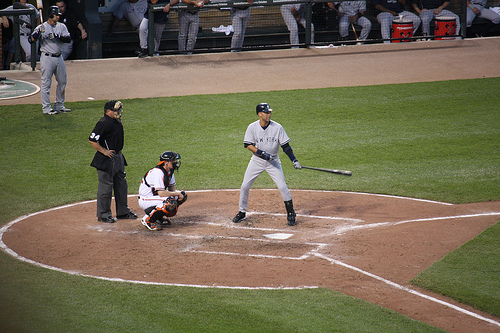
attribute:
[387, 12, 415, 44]
cooler — red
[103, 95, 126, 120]
mask — white, face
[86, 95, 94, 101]
spot — white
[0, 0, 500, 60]
people — sitting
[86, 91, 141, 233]
umpire — all in black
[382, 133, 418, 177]
ground — marked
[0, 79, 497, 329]
grass — short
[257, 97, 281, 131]
head — man's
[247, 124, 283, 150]
uniform — gray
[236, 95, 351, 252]
man — wearing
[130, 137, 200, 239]
man — wearing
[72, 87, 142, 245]
man — wearing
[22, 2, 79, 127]
man — wearing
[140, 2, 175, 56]
man — wearing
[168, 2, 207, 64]
man — wearing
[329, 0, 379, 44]
man — wearing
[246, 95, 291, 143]
baseball player — Yankees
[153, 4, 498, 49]
fence — black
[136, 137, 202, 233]
catcher — crouched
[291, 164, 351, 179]
bat — baseball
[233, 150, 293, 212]
pants — player's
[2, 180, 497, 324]
chalk — white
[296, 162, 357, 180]
bat — large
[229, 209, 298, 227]
shoes — black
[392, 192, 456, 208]
color — white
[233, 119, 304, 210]
dress — sports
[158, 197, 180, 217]
pad — knee